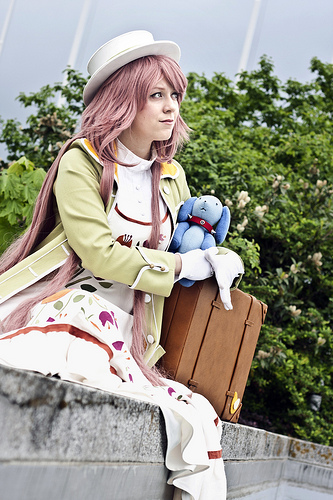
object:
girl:
[0, 31, 244, 499]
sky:
[0, 2, 332, 164]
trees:
[0, 52, 332, 447]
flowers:
[234, 189, 251, 210]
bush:
[0, 52, 332, 449]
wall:
[0, 365, 332, 499]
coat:
[0, 134, 244, 373]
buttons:
[146, 334, 155, 346]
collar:
[186, 213, 216, 240]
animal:
[170, 189, 230, 290]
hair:
[0, 57, 196, 388]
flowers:
[98, 311, 121, 328]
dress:
[0, 135, 227, 499]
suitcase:
[158, 278, 268, 425]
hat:
[82, 27, 181, 111]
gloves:
[203, 248, 246, 313]